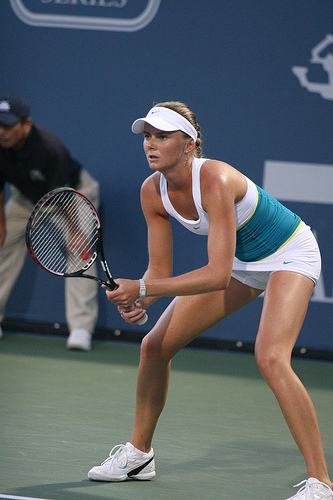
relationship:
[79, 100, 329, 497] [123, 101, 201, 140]
woman wearing hat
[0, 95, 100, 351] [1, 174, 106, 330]
man wearing pants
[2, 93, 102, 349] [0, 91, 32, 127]
man wearing hat